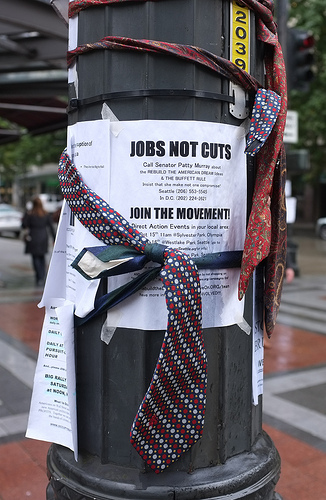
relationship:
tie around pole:
[57, 151, 209, 471] [45, 2, 282, 497]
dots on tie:
[152, 283, 236, 333] [57, 151, 209, 471]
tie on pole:
[57, 151, 209, 471] [73, 8, 272, 130]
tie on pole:
[57, 151, 209, 471] [45, 2, 282, 497]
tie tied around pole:
[57, 151, 209, 471] [52, 3, 299, 476]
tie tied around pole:
[57, 151, 209, 471] [45, 2, 282, 497]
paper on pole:
[109, 117, 248, 330] [65, 14, 292, 325]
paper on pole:
[22, 296, 78, 459] [65, 14, 292, 325]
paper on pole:
[36, 119, 112, 315] [65, 14, 292, 325]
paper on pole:
[250, 254, 263, 401] [65, 14, 292, 325]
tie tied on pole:
[57, 151, 209, 471] [45, 2, 282, 497]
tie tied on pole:
[63, 32, 290, 340] [45, 2, 282, 497]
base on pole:
[43, 445, 279, 498] [45, 2, 282, 497]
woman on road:
[10, 201, 61, 268] [1, 218, 324, 288]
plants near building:
[0, 129, 64, 201] [0, 0, 69, 138]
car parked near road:
[0, 192, 39, 233] [6, 251, 21, 307]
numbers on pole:
[223, 3, 253, 87] [45, 2, 282, 497]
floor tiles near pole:
[275, 338, 312, 367] [45, 2, 282, 497]